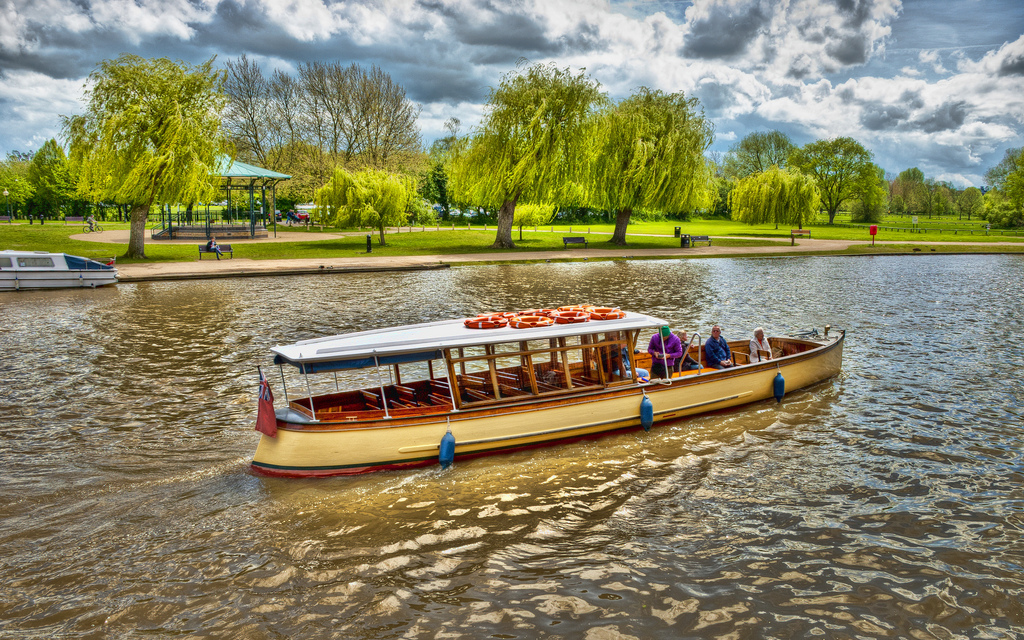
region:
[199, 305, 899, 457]
tan and red boat in river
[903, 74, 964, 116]
white clouds in blue sky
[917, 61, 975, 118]
white clouds in blue sky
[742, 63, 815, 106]
white clouds in blue sky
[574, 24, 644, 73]
white clouds in blue sky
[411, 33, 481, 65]
white clouds in blue sky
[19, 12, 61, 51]
white clouds in blue sky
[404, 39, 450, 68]
white clouds in blue sky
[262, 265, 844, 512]
boat is on water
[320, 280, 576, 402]
white top on boat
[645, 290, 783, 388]
people sitting in boat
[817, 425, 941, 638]
small ripples on water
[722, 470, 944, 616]
water is clear and reflective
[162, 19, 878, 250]
green trees on shore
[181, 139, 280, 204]
green canopy in distance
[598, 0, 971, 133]
white and grey clouds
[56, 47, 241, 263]
a tree in a field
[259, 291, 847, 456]
a boat on the water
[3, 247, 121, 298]
a boat on the water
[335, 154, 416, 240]
a tree in a field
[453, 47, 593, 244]
a tree in a field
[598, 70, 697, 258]
a tree in a field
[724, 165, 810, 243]
a tree in a field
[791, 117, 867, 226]
a tree in a field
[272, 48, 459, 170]
a tree in a field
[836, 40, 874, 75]
white clouds in blue sky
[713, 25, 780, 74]
white clouds in blue sky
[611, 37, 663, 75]
white clouds in blue sky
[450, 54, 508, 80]
white clouds in blue sky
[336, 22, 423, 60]
white clouds in blue sky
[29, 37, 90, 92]
white clouds in blue sky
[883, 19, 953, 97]
white clouds in blue sky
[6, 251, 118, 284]
A small boat docked on the bank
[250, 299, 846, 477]
A large boat carrying passengers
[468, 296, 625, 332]
Life tubes on top of the boat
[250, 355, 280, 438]
A flag hanging limply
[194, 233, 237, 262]
A bench with a person sitting on it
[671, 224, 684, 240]
A trash can in the park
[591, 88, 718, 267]
A weeping willow tree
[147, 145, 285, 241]
A structure with a roof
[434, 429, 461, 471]
A floating device hanging on the side of a boat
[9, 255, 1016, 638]
A body of water with boats on it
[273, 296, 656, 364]
the roof is white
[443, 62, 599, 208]
the branches are long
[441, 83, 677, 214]
a tree that is green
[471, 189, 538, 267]
the trunk of a tree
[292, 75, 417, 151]
a bunch of branches on a tree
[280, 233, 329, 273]
grass that is green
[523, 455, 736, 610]
ripples in some brown water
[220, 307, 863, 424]
boat in the water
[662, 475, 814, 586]
water under the boat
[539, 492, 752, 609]
ripples in the water